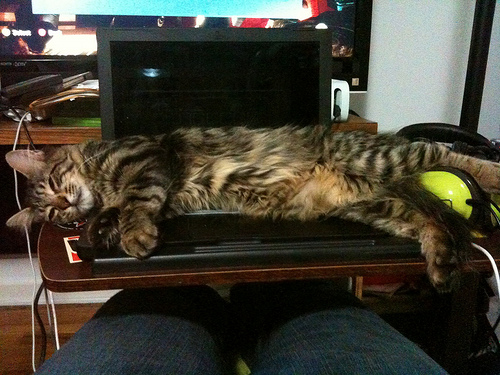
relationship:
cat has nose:
[23, 122, 463, 248] [62, 193, 78, 213]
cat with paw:
[23, 122, 463, 248] [116, 198, 157, 255]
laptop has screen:
[89, 25, 350, 128] [315, 34, 343, 121]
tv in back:
[21, 26, 56, 49] [421, 17, 446, 43]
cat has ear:
[23, 122, 463, 248] [11, 132, 55, 187]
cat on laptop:
[23, 122, 463, 248] [89, 25, 350, 128]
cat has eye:
[23, 122, 463, 248] [38, 167, 66, 192]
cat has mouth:
[23, 122, 463, 248] [70, 184, 93, 217]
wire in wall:
[27, 251, 44, 288] [412, 63, 438, 111]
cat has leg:
[23, 122, 463, 248] [342, 136, 497, 180]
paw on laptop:
[116, 198, 157, 255] [89, 25, 350, 128]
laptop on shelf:
[89, 25, 350, 128] [42, 125, 86, 149]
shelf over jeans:
[42, 125, 86, 149] [70, 301, 411, 374]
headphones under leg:
[421, 175, 490, 225] [342, 136, 497, 180]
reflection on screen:
[139, 55, 167, 97] [315, 34, 343, 121]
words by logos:
[15, 26, 31, 42] [38, 21, 48, 42]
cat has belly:
[23, 122, 463, 248] [187, 159, 357, 210]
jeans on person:
[70, 301, 411, 374] [252, 345, 372, 366]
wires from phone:
[5, 134, 31, 212] [28, 96, 104, 121]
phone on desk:
[28, 96, 104, 121] [1, 59, 72, 129]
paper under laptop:
[67, 237, 87, 265] [89, 25, 350, 128]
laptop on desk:
[89, 25, 350, 128] [1, 59, 72, 129]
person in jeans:
[252, 345, 372, 366] [70, 301, 411, 374]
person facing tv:
[252, 345, 372, 366] [21, 26, 56, 49]